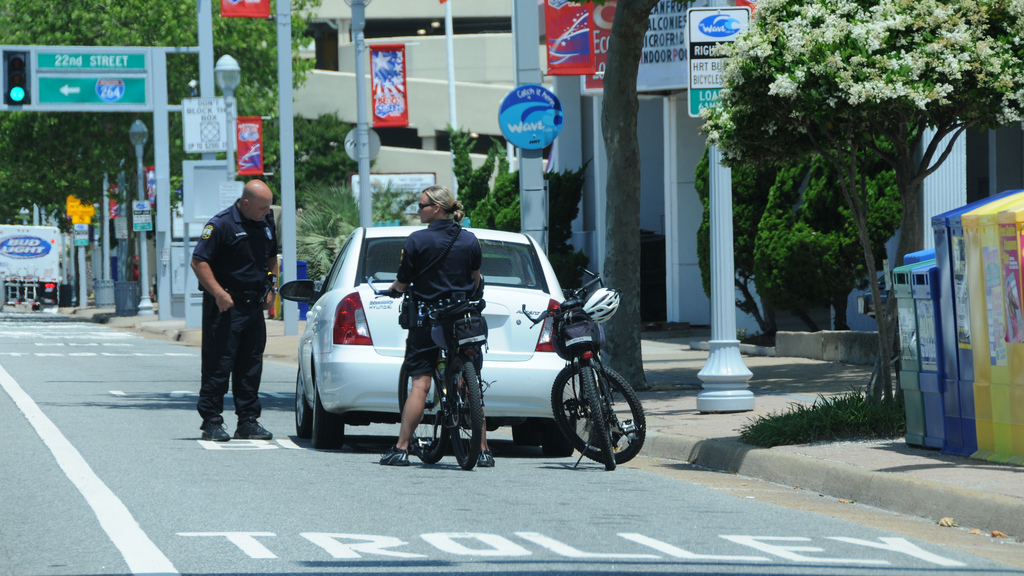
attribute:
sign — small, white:
[691, 11, 752, 87]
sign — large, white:
[634, 3, 699, 93]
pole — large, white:
[698, 131, 756, 413]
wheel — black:
[306, 374, 341, 448]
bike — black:
[517, 286, 644, 470]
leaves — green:
[728, 81, 876, 177]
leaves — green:
[743, 27, 912, 159]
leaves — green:
[717, 100, 899, 202]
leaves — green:
[747, 119, 916, 294]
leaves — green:
[722, 14, 857, 248]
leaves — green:
[756, 13, 901, 201]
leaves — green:
[754, 126, 873, 302]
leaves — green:
[747, 139, 873, 250]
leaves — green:
[797, 9, 873, 254]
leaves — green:
[786, 1, 987, 99]